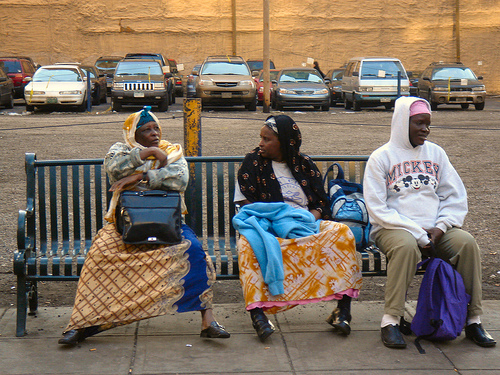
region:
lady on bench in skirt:
[63, 114, 238, 333]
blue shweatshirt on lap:
[219, 121, 348, 291]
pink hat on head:
[376, 64, 465, 176]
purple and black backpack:
[400, 243, 475, 356]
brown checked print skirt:
[67, 231, 174, 334]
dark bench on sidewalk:
[7, 145, 116, 369]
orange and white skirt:
[233, 117, 384, 319]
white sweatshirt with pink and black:
[357, 84, 471, 236]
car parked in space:
[8, 59, 115, 121]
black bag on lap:
[99, 105, 217, 281]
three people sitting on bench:
[106, 111, 488, 340]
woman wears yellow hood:
[97, 109, 180, 154]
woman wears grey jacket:
[100, 146, 200, 206]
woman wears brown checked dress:
[72, 200, 214, 335]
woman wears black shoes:
[50, 318, 240, 334]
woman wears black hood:
[265, 116, 303, 146]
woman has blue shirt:
[240, 180, 335, 289]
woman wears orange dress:
[245, 226, 362, 320]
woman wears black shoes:
[248, 290, 362, 345]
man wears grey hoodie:
[381, 77, 468, 240]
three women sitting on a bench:
[97, 87, 496, 232]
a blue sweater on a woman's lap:
[222, 182, 317, 265]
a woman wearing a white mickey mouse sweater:
[375, 103, 449, 241]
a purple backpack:
[411, 227, 472, 344]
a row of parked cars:
[13, 41, 498, 122]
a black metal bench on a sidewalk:
[3, 151, 92, 291]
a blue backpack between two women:
[328, 173, 378, 248]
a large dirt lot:
[10, 120, 120, 158]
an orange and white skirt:
[277, 236, 362, 297]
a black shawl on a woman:
[258, 121, 325, 201]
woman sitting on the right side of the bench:
[360, 94, 497, 358]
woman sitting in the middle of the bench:
[227, 114, 361, 339]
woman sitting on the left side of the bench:
[57, 104, 234, 348]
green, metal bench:
[12, 151, 439, 340]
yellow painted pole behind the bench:
[175, 96, 207, 236]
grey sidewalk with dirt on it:
[3, 295, 496, 374]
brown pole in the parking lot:
[258, 1, 273, 113]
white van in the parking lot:
[340, 54, 413, 116]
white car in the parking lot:
[20, 59, 97, 115]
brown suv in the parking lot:
[197, 49, 257, 113]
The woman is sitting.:
[51, 99, 233, 363]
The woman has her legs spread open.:
[50, 108, 230, 356]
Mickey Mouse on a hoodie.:
[359, 83, 479, 257]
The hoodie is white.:
[361, 72, 472, 247]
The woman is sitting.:
[229, 104, 365, 349]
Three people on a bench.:
[8, 95, 498, 355]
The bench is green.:
[9, 145, 454, 340]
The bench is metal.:
[8, 142, 475, 342]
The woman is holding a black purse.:
[87, 102, 205, 254]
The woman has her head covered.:
[87, 104, 196, 186]